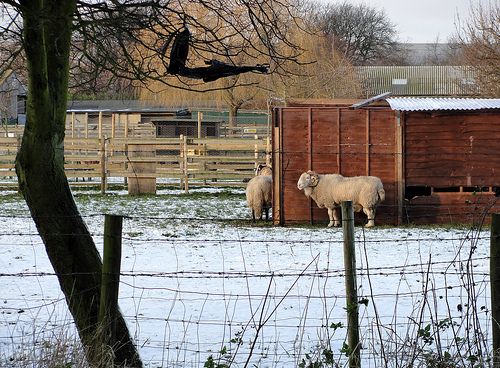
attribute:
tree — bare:
[1, 0, 318, 365]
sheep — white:
[295, 166, 387, 229]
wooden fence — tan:
[64, 133, 271, 193]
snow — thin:
[1, 191, 493, 366]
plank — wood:
[344, 87, 391, 107]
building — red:
[265, 90, 490, 232]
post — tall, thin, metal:
[337, 198, 362, 367]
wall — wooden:
[433, 128, 465, 178]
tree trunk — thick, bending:
[4, 28, 152, 365]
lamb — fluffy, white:
[242, 160, 277, 222]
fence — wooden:
[2, 141, 265, 189]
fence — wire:
[3, 206, 499, 366]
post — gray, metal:
[322, 189, 381, 366]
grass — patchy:
[0, 178, 490, 253]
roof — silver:
[381, 97, 498, 119]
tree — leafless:
[187, 25, 273, 75]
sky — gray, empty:
[378, 1, 494, 38]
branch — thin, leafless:
[170, 8, 240, 67]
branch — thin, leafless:
[148, 74, 263, 91]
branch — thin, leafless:
[72, 45, 152, 85]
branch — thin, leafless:
[247, 6, 304, 67]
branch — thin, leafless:
[275, 1, 329, 40]